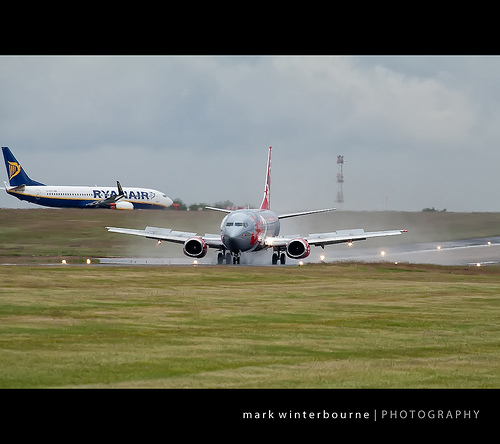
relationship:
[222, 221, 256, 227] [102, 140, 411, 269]
cockpit of plane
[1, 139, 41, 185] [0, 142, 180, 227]
blue tail of plane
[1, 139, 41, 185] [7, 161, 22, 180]
blue tail with logo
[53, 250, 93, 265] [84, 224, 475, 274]
illuminated lights on runway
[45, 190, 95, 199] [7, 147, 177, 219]
row of windows on plane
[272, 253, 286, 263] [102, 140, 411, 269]
black wheel of plane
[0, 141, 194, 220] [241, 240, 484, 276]
plane on runway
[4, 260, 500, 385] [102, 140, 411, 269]
some grass near plane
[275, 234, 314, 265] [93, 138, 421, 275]
engine on plane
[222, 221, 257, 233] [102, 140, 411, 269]
cockpit on plane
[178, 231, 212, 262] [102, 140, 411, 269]
engine on plane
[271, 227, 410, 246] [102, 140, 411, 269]
wing on plane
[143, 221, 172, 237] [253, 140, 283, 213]
rudder on plane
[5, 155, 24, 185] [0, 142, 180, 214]
logo on plane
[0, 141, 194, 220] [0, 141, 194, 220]
plane taking off plane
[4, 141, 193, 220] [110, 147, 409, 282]
plane plane says plane